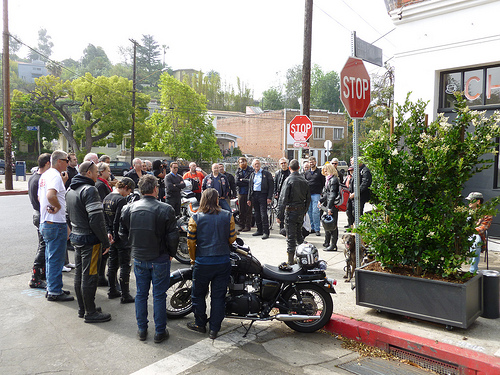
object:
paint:
[339, 315, 371, 341]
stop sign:
[342, 76, 370, 99]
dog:
[341, 234, 366, 283]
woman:
[187, 188, 237, 339]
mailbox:
[15, 160, 25, 181]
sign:
[26, 125, 37, 131]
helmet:
[321, 214, 335, 231]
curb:
[273, 307, 499, 375]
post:
[300, 0, 313, 158]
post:
[128, 39, 142, 167]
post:
[2, 0, 13, 190]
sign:
[338, 55, 371, 119]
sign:
[289, 115, 314, 147]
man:
[117, 174, 181, 344]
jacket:
[117, 195, 178, 260]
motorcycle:
[166, 244, 337, 338]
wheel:
[172, 231, 191, 264]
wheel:
[279, 282, 333, 333]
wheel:
[165, 268, 191, 319]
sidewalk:
[292, 235, 499, 370]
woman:
[316, 162, 349, 251]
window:
[462, 68, 484, 105]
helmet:
[294, 241, 317, 270]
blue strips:
[186, 229, 196, 240]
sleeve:
[187, 218, 198, 265]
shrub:
[357, 91, 500, 282]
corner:
[336, 277, 361, 316]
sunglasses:
[59, 157, 70, 163]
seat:
[263, 263, 303, 282]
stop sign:
[290, 123, 311, 133]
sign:
[356, 36, 383, 67]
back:
[324, 140, 332, 150]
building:
[217, 108, 349, 171]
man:
[37, 149, 74, 301]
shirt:
[37, 168, 66, 225]